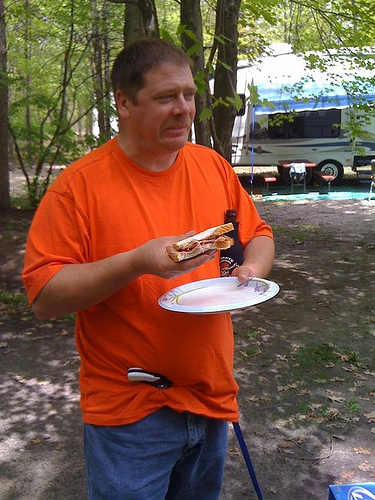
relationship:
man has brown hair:
[22, 40, 275, 500] [101, 34, 202, 99]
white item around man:
[121, 342, 184, 396] [46, 40, 285, 455]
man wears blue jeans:
[22, 40, 275, 500] [74, 418, 234, 494]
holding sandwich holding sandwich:
[164, 209, 242, 267] [161, 195, 232, 271]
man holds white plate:
[62, 27, 278, 420] [147, 272, 290, 331]